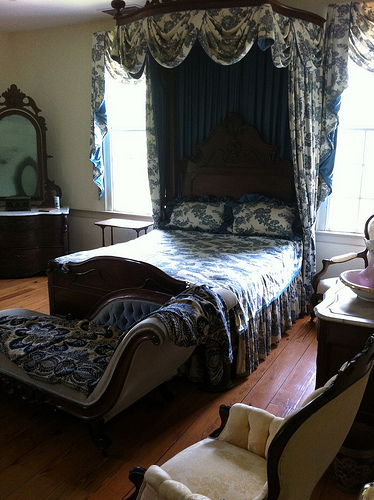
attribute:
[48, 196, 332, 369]
bed — is white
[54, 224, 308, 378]
cover — blue , white 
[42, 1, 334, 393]
bed — large 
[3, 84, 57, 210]
mirror — black, old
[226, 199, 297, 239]
pillow — white, blue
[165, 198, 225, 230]
pillow — white, blue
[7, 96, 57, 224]
mirror — large 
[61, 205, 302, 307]
bedspread — white 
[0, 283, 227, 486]
couch — wood, grey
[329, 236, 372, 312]
bowl — basin    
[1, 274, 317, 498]
floor — wooden 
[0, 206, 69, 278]
dresser — dark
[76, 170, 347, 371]
cot — wooden 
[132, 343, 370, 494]
chair — is antique, is white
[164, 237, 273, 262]
fabric — is blue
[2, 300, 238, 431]
chair — is wooden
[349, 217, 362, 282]
pitcher — White 